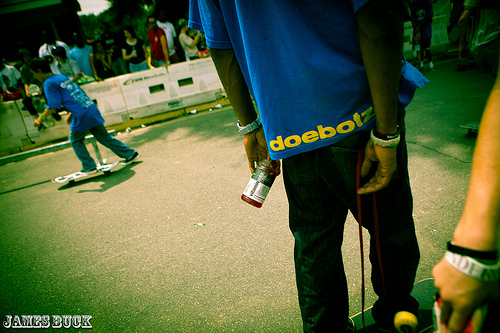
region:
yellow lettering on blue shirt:
[269, 99, 376, 155]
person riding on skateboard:
[26, 55, 143, 192]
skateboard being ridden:
[53, 154, 114, 186]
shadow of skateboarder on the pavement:
[73, 169, 140, 195]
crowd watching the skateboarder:
[8, 5, 192, 78]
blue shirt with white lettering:
[40, 74, 105, 130]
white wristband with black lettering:
[440, 246, 499, 284]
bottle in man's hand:
[237, 152, 279, 205]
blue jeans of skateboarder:
[64, 121, 134, 162]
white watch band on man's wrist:
[234, 114, 257, 135]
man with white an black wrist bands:
[422, 232, 497, 331]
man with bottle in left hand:
[225, 132, 282, 210]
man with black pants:
[264, 115, 386, 327]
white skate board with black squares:
[46, 154, 124, 201]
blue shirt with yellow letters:
[258, 98, 372, 158]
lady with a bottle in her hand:
[119, 22, 141, 88]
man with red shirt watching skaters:
[145, 24, 173, 73]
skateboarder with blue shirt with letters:
[34, 64, 105, 136]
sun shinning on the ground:
[44, 185, 189, 297]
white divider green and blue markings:
[100, 53, 212, 118]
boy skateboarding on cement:
[21, 40, 149, 196]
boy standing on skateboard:
[41, 154, 144, 195]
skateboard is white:
[48, 160, 138, 187]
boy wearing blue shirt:
[21, 48, 155, 173]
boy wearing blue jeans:
[68, 113, 142, 177]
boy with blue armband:
[34, 110, 51, 123]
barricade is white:
[108, 62, 219, 109]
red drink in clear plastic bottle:
[230, 142, 285, 212]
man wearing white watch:
[226, 112, 269, 139]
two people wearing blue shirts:
[21, 8, 439, 331]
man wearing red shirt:
[145, 18, 171, 60]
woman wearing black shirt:
[120, 32, 147, 67]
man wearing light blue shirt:
[66, 32, 96, 77]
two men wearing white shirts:
[36, 12, 177, 79]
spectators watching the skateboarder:
[4, 3, 191, 93]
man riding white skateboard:
[23, 58, 137, 193]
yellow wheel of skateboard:
[391, 305, 424, 331]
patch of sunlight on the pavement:
[5, 137, 485, 292]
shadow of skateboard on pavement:
[73, 161, 140, 200]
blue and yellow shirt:
[206, 20, 411, 150]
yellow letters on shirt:
[265, 102, 407, 177]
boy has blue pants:
[294, 144, 419, 328]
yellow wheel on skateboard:
[367, 291, 433, 327]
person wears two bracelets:
[452, 239, 494, 283]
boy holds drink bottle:
[220, 145, 290, 225]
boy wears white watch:
[235, 107, 267, 148]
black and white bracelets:
[351, 100, 411, 169]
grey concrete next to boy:
[131, 176, 238, 304]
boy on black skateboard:
[322, 264, 454, 326]